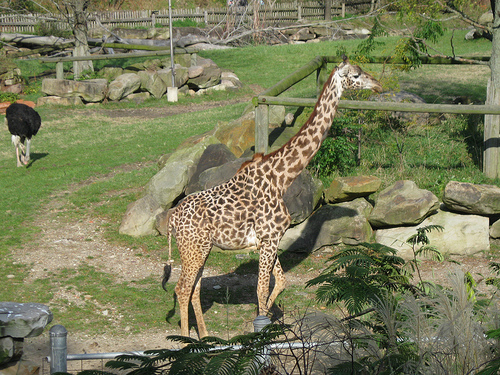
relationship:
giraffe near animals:
[162, 54, 390, 348] [5, 101, 41, 168]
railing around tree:
[253, 55, 500, 176] [335, 0, 499, 182]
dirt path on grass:
[1, 83, 499, 374] [0, 27, 500, 336]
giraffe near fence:
[162, 54, 390, 348] [42, 315, 487, 375]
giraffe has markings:
[162, 54, 390, 348] [161, 55, 384, 346]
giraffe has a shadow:
[162, 54, 390, 348] [166, 197, 360, 341]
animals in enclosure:
[6, 56, 384, 347] [1, 0, 500, 372]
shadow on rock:
[166, 197, 360, 341] [277, 196, 376, 255]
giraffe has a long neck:
[162, 54, 390, 348] [284, 71, 344, 191]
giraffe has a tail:
[162, 54, 390, 348] [161, 208, 177, 294]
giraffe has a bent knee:
[162, 54, 390, 348] [273, 269, 287, 294]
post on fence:
[49, 324, 67, 374] [42, 315, 487, 375]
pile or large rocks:
[36, 52, 241, 99] [36, 53, 241, 98]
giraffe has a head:
[162, 54, 390, 348] [336, 55, 383, 95]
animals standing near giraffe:
[5, 101, 41, 168] [162, 54, 390, 348]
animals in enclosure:
[5, 101, 41, 168] [1, 0, 500, 372]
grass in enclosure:
[0, 27, 500, 336] [1, 0, 500, 372]